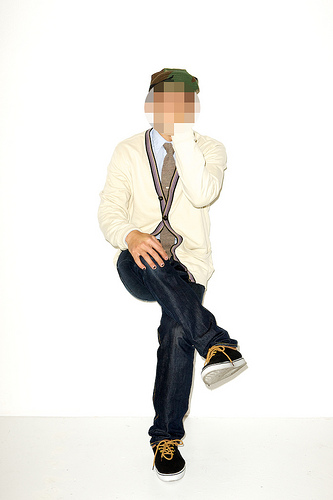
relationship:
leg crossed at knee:
[117, 248, 220, 350] [134, 249, 202, 356]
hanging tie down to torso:
[158, 141, 177, 259] [111, 126, 217, 256]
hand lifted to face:
[166, 92, 199, 159] [150, 86, 191, 139]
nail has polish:
[158, 261, 164, 267] [160, 264, 162, 266]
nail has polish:
[150, 264, 157, 268] [153, 266, 155, 268]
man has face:
[97, 67, 246, 481] [141, 81, 201, 135]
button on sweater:
[156, 194, 165, 200] [94, 122, 234, 285]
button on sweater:
[160, 213, 169, 222] [94, 122, 234, 285]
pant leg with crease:
[147, 313, 194, 440] [164, 337, 178, 435]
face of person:
[145, 76, 199, 137] [90, 39, 236, 322]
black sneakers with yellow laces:
[146, 432, 181, 470] [147, 437, 181, 466]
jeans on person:
[111, 244, 241, 450] [90, 63, 249, 485]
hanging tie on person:
[160, 143, 175, 258] [81, 49, 292, 499]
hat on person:
[141, 64, 209, 93] [75, 45, 259, 362]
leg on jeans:
[173, 288, 207, 326] [144, 270, 204, 366]